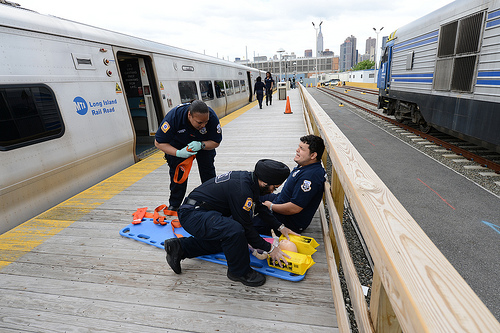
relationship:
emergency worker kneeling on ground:
[164, 159, 301, 287] [0, 87, 498, 332]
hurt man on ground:
[283, 123, 333, 243] [222, 124, 294, 161]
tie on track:
[259, 177, 299, 216] [312, 85, 496, 309]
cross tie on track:
[425, 141, 441, 151] [317, 77, 499, 204]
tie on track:
[409, 135, 421, 145] [317, 83, 499, 185]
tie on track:
[461, 162, 484, 172] [459, 145, 486, 175]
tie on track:
[440, 150, 463, 160] [316, 78, 497, 178]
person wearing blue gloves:
[159, 105, 239, 161] [162, 137, 210, 167]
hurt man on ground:
[230, 134, 327, 236] [3, 77, 345, 331]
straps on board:
[129, 198, 186, 236] [113, 207, 311, 294]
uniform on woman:
[160, 116, 190, 143] [154, 98, 223, 209]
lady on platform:
[248, 70, 270, 113] [223, 107, 286, 182]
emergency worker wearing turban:
[164, 159, 301, 287] [245, 152, 290, 184]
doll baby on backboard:
[252, 229, 297, 254] [119, 218, 306, 282]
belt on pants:
[182, 197, 204, 207] [177, 196, 253, 281]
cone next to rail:
[283, 96, 290, 113] [295, 81, 499, 331]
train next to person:
[31, 0, 308, 160] [161, 87, 225, 245]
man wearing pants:
[162, 106, 403, 283] [161, 199, 289, 267]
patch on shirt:
[300, 179, 313, 194] [273, 162, 326, 232]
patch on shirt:
[242, 198, 256, 211] [188, 169, 283, 254]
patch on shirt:
[157, 122, 172, 134] [153, 103, 223, 150]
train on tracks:
[379, 0, 499, 155] [314, 79, 498, 202]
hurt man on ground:
[230, 134, 327, 236] [0, 87, 498, 332]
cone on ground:
[284, 96, 293, 114] [3, 77, 345, 331]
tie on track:
[330, 96, 499, 187] [316, 78, 497, 178]